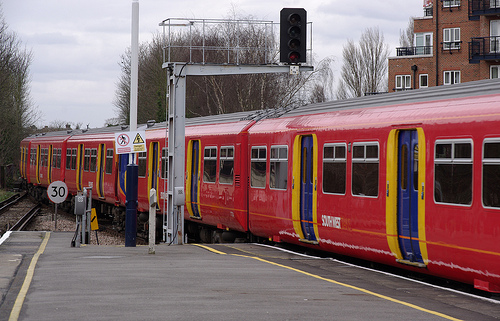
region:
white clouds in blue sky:
[19, 14, 41, 41]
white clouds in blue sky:
[49, 35, 71, 67]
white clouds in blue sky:
[79, 31, 119, 79]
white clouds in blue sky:
[52, 33, 97, 88]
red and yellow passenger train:
[336, 97, 482, 284]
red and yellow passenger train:
[240, 103, 480, 244]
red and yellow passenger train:
[176, 130, 256, 226]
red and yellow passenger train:
[33, 125, 103, 185]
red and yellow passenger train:
[257, 118, 375, 235]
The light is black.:
[273, 5, 312, 70]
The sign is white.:
[105, 123, 147, 153]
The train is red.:
[18, 80, 498, 287]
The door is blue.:
[393, 128, 421, 263]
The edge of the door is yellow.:
[379, 123, 429, 268]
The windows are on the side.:
[44, 148, 499, 210]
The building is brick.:
[374, 7, 497, 87]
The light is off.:
[274, 0, 306, 66]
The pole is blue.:
[121, 167, 141, 248]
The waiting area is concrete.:
[5, 228, 445, 317]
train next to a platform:
[11, 71, 499, 306]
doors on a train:
[380, 120, 435, 267]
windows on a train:
[316, 131, 378, 201]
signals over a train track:
[273, 1, 314, 73]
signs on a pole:
[109, 125, 153, 157]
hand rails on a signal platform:
[160, 10, 278, 70]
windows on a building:
[439, 23, 465, 56]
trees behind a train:
[333, 17, 393, 101]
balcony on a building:
[381, 26, 432, 58]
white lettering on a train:
[317, 211, 342, 231]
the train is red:
[24, 120, 450, 282]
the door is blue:
[381, 128, 443, 276]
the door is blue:
[283, 135, 316, 246]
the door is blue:
[79, 142, 264, 239]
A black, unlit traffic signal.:
[277, 5, 309, 67]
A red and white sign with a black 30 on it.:
[44, 176, 69, 204]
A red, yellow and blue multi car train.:
[17, 69, 497, 296]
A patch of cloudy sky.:
[35, 22, 105, 98]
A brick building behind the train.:
[385, 0, 497, 95]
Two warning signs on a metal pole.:
[112, 128, 151, 160]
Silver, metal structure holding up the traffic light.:
[157, 13, 317, 245]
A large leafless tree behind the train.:
[111, 3, 312, 123]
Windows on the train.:
[319, 136, 382, 198]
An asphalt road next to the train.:
[7, 227, 497, 319]